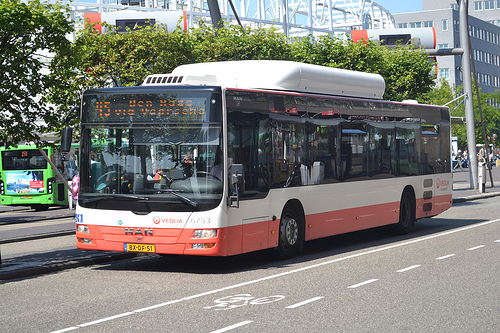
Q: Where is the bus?
A: In the street.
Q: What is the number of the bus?
A: 45.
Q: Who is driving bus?
A: A man.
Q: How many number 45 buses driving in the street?
A: One.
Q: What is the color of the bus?
A: White and orange.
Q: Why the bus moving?
A: To go to next station.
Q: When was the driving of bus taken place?
A: Daytime.